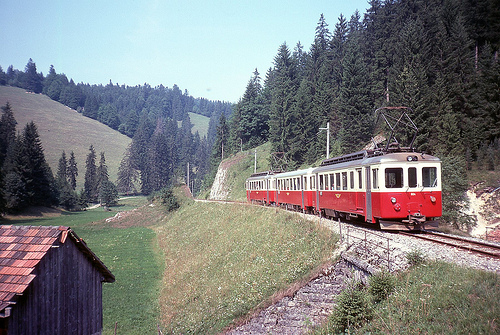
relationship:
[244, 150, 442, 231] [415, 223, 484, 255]
car on tracks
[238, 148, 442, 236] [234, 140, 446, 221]
car on train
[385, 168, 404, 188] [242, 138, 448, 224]
window on train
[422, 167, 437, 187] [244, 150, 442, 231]
window on car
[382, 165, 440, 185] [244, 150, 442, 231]
window on car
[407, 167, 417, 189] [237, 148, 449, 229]
window on train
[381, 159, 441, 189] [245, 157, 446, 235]
window on train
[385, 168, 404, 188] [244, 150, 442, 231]
window on car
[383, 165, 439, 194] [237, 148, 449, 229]
window on train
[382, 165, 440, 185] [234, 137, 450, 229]
window on train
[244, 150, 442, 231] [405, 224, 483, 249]
car on tracks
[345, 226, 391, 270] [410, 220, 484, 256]
fence on tracks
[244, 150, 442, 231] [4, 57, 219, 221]
car in hillside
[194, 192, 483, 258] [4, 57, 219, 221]
track though hillside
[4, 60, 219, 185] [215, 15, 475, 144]
hillside covered trees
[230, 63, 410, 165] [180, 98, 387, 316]
trees on hills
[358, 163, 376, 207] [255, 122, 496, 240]
doors on train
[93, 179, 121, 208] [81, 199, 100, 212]
tree by road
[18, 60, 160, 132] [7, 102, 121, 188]
trees are on hill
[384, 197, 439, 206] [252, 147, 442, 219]
lights are on train